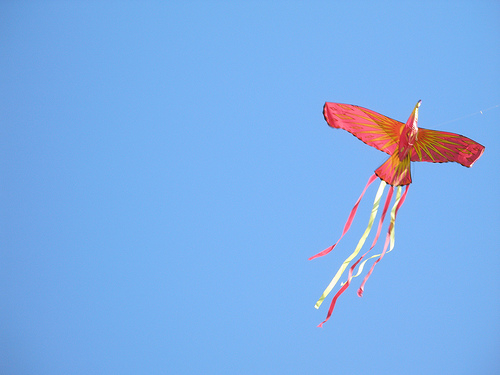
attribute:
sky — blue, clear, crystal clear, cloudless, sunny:
[2, 1, 479, 372]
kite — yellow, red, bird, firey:
[321, 96, 484, 189]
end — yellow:
[413, 95, 423, 112]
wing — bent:
[457, 138, 484, 170]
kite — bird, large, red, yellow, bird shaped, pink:
[301, 92, 484, 338]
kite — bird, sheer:
[309, 95, 482, 326]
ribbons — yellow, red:
[303, 173, 411, 332]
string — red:
[308, 173, 378, 263]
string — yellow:
[312, 181, 385, 311]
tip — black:
[321, 99, 333, 123]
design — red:
[451, 139, 476, 162]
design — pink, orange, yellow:
[412, 129, 466, 159]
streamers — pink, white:
[303, 172, 413, 332]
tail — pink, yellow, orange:
[372, 152, 415, 188]